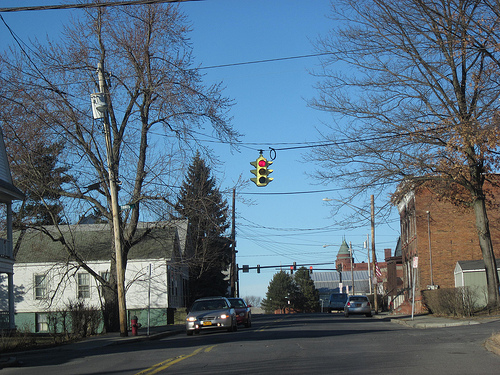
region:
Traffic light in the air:
[249, 151, 273, 186]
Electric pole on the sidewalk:
[88, 60, 128, 337]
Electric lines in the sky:
[1, 12, 498, 264]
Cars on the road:
[181, 289, 373, 334]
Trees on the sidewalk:
[2, 1, 499, 333]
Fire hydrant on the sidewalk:
[129, 312, 143, 334]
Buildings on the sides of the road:
[0, 167, 499, 335]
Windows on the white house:
[34, 271, 104, 299]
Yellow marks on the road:
[127, 316, 278, 373]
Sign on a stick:
[410, 255, 418, 317]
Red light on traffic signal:
[216, 135, 336, 210]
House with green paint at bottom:
[8, 215, 185, 335]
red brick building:
[379, 171, 497, 316]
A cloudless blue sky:
[171, 50, 396, 272]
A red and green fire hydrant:
[112, 302, 164, 339]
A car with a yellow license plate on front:
[175, 280, 236, 330]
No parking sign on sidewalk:
[365, 245, 456, 335]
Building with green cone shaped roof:
[315, 225, 377, 277]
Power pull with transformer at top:
[60, 56, 150, 348]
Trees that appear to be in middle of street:
[195, 241, 406, 331]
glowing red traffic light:
[248, 145, 275, 187]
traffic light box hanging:
[250, 146, 282, 188]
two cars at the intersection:
[183, 290, 256, 342]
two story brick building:
[380, 167, 499, 317]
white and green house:
[9, 212, 206, 335]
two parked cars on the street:
[323, 284, 379, 319]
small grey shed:
[447, 254, 499, 314]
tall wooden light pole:
[80, 56, 152, 341]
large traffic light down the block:
[229, 242, 368, 311]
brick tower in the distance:
[332, 228, 402, 279]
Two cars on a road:
[168, 286, 283, 343]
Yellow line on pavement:
[150, 333, 232, 374]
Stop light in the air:
[235, 132, 281, 192]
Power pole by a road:
[89, 177, 162, 345]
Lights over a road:
[251, 238, 364, 309]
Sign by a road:
[398, 252, 438, 322]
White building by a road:
[43, 222, 210, 362]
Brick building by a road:
[332, 230, 386, 303]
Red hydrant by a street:
[124, 309, 145, 342]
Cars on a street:
[161, 273, 265, 352]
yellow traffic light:
[242, 142, 278, 189]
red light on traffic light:
[257, 154, 268, 171]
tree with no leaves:
[10, 28, 187, 202]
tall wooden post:
[91, 55, 131, 355]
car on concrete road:
[182, 295, 237, 339]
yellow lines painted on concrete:
[141, 340, 226, 372]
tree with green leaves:
[255, 257, 315, 317]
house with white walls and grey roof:
[0, 221, 185, 321]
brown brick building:
[395, 165, 495, 285]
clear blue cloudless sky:
[205, 19, 302, 63]